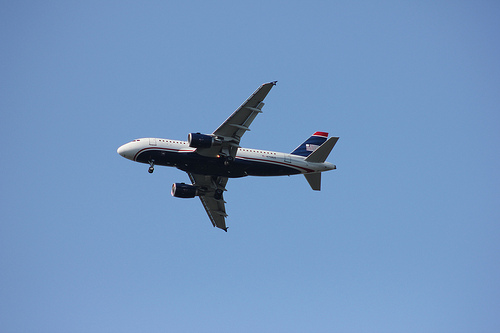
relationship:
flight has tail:
[116, 80, 340, 232] [294, 117, 342, 196]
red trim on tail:
[308, 127, 328, 143] [291, 129, 336, 162]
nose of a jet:
[115, 142, 132, 157] [110, 99, 340, 198]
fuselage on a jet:
[146, 139, 326, 173] [116, 81, 339, 231]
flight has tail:
[116, 80, 340, 232] [289, 122, 343, 196]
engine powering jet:
[185, 128, 217, 150] [116, 81, 339, 231]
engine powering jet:
[168, 180, 200, 202] [116, 81, 339, 231]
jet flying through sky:
[116, 81, 339, 231] [14, 14, 483, 331]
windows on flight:
[241, 146, 296, 171] [116, 80, 340, 232]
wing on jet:
[193, 80, 277, 159] [116, 81, 339, 231]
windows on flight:
[129, 135, 141, 143] [116, 80, 340, 232]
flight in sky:
[116, 80, 340, 232] [14, 14, 483, 331]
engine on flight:
[188, 132, 223, 149] [116, 80, 340, 232]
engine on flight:
[171, 182, 200, 198] [116, 80, 340, 232]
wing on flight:
[194, 80, 278, 158] [116, 80, 340, 232]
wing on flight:
[192, 175, 231, 234] [116, 80, 340, 232]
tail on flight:
[289, 126, 340, 192] [116, 80, 340, 232]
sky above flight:
[14, 14, 483, 331] [116, 80, 340, 232]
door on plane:
[147, 137, 157, 146] [111, 71, 358, 253]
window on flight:
[159, 139, 166, 142] [116, 80, 340, 232]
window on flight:
[165, 138, 170, 142] [116, 80, 340, 232]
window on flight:
[172, 140, 176, 144] [116, 80, 340, 232]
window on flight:
[183, 142, 188, 145] [116, 80, 340, 232]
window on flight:
[238, 147, 243, 152] [116, 80, 340, 232]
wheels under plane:
[189, 130, 240, 209] [58, 73, 371, 242]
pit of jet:
[113, 128, 149, 163] [124, 136, 141, 153]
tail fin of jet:
[288, 130, 328, 157] [116, 81, 339, 231]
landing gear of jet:
[140, 145, 164, 171] [116, 81, 339, 231]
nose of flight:
[116, 146, 131, 157] [116, 80, 340, 232]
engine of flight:
[188, 132, 223, 149] [116, 80, 340, 232]